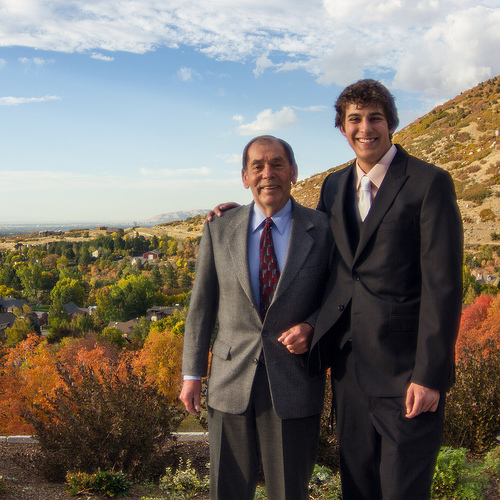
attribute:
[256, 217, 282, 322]
tie — hanging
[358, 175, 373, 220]
tie — white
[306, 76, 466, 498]
man — is in foreground, taller, dark brown, curly brown haired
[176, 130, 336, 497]
man — is in foreground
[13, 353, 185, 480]
bush — small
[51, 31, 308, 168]
sky — blue, white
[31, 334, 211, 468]
tree — fall colored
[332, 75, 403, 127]
curly hair — dark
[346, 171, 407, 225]
tie — knotted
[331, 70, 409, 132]
hair — curly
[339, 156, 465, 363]
suit — grey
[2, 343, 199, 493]
tree — fall colored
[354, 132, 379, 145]
smile — toothy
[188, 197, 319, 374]
jacket — black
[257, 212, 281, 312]
tie — red and grey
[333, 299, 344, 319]
button — black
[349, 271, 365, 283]
button — black